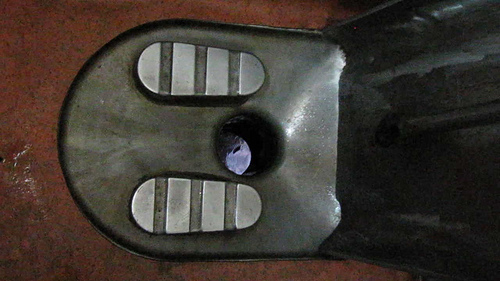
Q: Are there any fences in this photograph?
A: No, there are no fences.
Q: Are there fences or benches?
A: No, there are no fences or benches.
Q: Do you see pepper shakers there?
A: No, there are no pepper shakers.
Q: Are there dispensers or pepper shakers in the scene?
A: No, there are no pepper shakers or dispensers.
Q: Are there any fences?
A: No, there are no fences.